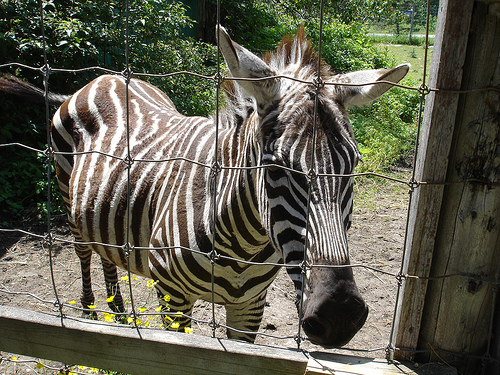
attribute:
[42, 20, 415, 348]
animal — black, white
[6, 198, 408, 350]
dirt — brown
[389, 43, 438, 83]
grass — green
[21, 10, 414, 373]
zebra — striped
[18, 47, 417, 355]
zebra — black, white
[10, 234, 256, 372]
flowers — yellow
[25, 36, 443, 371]
zebra — sunbathed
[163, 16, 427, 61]
foliage — green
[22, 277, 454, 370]
post — sundrenched, wooden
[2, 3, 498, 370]
fence — wooden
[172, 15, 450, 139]
ears — in a pair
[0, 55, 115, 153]
tail — in air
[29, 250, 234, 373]
flowers — small, yellow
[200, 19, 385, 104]
hair — mohawk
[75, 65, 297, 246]
stripes — brown, not black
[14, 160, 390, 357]
grass — dead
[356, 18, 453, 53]
road — a walk way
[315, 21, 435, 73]
grass — over grown, green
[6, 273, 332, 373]
fence board — wooden, horizontal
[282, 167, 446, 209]
grass — green, patchy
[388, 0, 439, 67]
sign post — wooden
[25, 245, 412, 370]
fence — partial